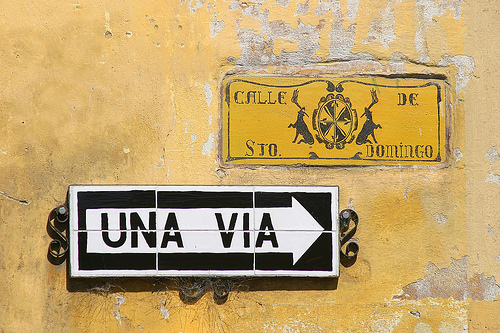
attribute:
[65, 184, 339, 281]
sign — black, white, black colored, black in color, street sign, one way, white colored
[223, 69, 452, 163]
sign — black, yellow, yellow colored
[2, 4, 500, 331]
building — painted yellow, painted, yellow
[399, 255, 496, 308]
concrete — peeling, cracking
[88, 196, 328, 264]
arrow — pointing right, white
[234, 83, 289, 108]
text — black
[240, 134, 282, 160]
text — black